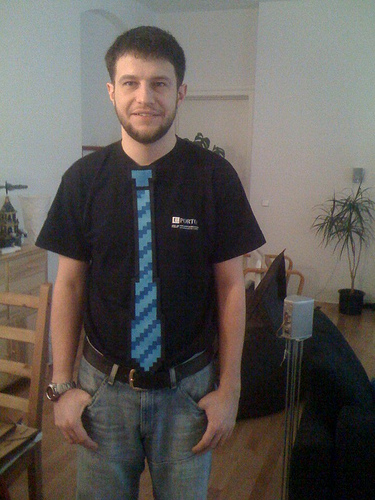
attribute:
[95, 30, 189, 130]
hair — short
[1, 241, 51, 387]
chest — tall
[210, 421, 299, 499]
floors — light, wood, hardwood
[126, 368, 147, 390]
clip — goden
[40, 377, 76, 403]
wristwatch — silver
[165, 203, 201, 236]
logo — white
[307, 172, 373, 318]
houseplant — tall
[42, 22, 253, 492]
man — bearded, smiling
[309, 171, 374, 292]
plant — green, mini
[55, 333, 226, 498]
jeans — worn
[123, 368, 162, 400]
belt — leather, black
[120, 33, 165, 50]
hair — dark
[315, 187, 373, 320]
plant — green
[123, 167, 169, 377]
tie — blue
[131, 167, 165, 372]
tie — pixelated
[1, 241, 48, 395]
shelf — wooden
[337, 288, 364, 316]
pot — black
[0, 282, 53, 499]
chair — wooden, light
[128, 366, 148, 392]
hinge — gold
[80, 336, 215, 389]
belt — leather